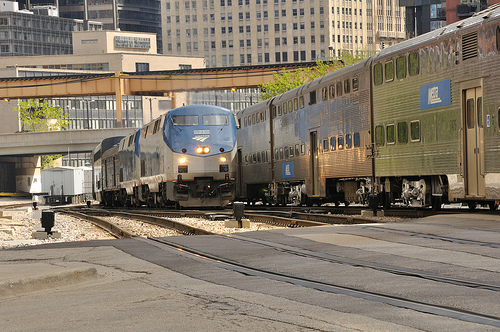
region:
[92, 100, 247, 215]
Large passenger train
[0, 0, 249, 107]
Various sized city buildings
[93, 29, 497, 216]
Two passenger trains ride passed in different directions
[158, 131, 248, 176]
Four bright lights on front of train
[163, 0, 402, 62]
The large building with many windows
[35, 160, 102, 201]
Utility buildings near train tracks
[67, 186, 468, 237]
Two out of three tracks have trains on them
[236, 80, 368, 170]
Passenger windows on the train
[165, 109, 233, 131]
Front windshield of passenger train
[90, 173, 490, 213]
Metallic wheels of the trains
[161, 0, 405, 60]
highrise apartment building in back ground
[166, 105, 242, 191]
front of train engine on tracks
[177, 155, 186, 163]
headlight on train engine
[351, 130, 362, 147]
air ventilation screen on cargo train car on track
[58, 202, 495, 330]
train tracks intersecting in train yard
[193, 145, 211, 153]
double headlights on train engine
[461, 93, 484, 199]
silver door to cargo compartment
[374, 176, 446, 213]
train wheels on cargo train carrier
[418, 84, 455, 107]
logo of company that owns the cargo car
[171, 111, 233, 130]
front windows on engine of the train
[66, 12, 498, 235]
double decker trains on tracks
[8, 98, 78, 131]
green leaves on a tree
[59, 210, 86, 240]
sand colored gravel by train tracks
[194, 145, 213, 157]
front lights of a train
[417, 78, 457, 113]
blue sign on a train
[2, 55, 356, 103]
overhead tracks by buildings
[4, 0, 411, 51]
buildings in the background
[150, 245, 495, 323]
train tracks the train rides on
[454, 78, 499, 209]
doorway to a train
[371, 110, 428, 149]
windows on a train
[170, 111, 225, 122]
windows on front of train.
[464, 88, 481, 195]
doors on side of train.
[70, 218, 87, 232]
pebbles next to the track.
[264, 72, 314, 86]
green leaves on trees.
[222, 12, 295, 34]
tall building in the background.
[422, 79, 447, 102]
blue sign on the train.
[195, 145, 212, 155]
lights on the front of the train.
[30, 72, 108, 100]
electrical wires above the train.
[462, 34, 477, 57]
vent on side of train.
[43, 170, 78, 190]
white building behind the train.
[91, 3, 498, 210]
two moving trains on the tracks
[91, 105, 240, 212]
blue and silver train on the tracks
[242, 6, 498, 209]
the side of train cars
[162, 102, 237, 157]
blue upper front on train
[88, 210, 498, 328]
railroad tracks on an asphalt road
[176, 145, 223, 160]
four lights glowing on front of blue train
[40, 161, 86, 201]
back of eighteen wheeler truck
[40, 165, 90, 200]
white back of a truck traveling under a bridge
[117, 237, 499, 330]
street with railroad tracks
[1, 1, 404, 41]
industrial buildings in the photo's background